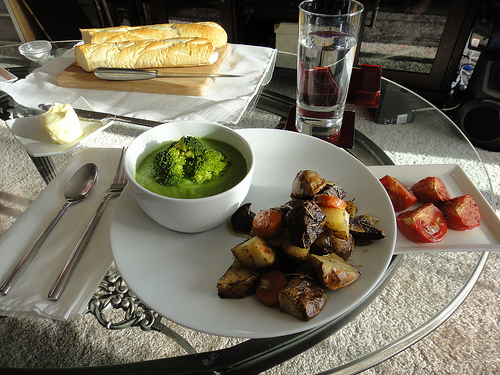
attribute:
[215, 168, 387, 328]
vegatables — baked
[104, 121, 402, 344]
plate — white, round, large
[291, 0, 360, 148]
glass — tall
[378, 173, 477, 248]
tomatoes — baked, sliced, roasted, grilled, red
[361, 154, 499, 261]
side plate — square, white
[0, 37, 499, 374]
table — glass, glass topped, round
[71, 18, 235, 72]
bread — baked, fresh, baguette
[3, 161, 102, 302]
spoon — shiny, very long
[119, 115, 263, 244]
bowl — white, round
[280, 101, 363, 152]
coaster — red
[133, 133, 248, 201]
broccoli soup — green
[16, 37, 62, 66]
container — small